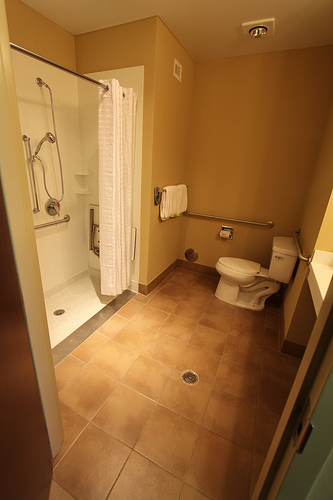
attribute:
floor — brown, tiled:
[127, 323, 226, 425]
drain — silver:
[180, 361, 201, 382]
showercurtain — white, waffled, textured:
[90, 93, 137, 210]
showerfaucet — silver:
[34, 101, 58, 162]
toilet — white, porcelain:
[210, 255, 268, 306]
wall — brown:
[210, 82, 298, 222]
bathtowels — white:
[159, 184, 191, 220]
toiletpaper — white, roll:
[218, 231, 235, 240]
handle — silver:
[203, 215, 273, 228]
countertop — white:
[299, 264, 331, 293]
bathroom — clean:
[4, 6, 332, 338]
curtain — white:
[101, 87, 144, 298]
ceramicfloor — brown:
[108, 305, 286, 375]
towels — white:
[164, 183, 202, 218]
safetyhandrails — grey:
[189, 203, 284, 235]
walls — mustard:
[182, 57, 310, 207]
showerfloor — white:
[36, 262, 112, 346]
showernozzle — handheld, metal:
[39, 132, 60, 175]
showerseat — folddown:
[84, 197, 116, 265]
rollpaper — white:
[216, 229, 232, 237]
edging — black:
[249, 26, 269, 38]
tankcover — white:
[267, 231, 302, 256]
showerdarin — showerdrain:
[56, 302, 66, 318]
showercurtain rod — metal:
[31, 217, 74, 235]